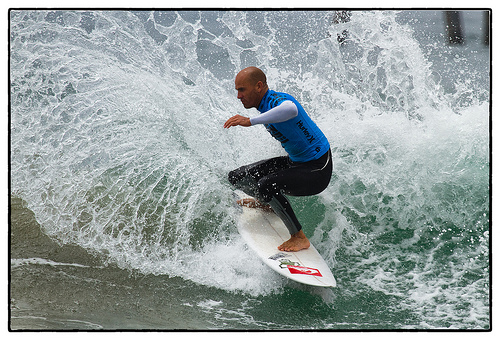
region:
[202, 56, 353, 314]
man surfing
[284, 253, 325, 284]
red logo on white board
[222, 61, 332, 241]
surfer in wet suit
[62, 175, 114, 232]
white and green ocean waves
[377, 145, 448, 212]
white and green ocean waves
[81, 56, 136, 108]
white and green ocean waves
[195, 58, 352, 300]
man riding on surf board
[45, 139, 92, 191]
white and green ocean waves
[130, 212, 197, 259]
white and green ocean waves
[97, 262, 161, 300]
white and green ocean waves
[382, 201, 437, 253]
white and green ocean waves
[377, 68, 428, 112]
white and green ocean waves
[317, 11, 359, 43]
white and green ocean waves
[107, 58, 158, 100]
white and green ocean waves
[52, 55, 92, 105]
white and green ocean waves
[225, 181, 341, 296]
white surfboard with red emblem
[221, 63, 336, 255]
man crouched on white surfboard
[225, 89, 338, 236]
blue white and black wetsuit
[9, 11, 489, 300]
large splash of crashing wave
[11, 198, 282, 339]
calm water preceding wave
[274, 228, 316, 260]
bare foot of man surfing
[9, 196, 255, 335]
dark brown ocean water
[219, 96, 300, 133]
curved hand at end of arm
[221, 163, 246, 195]
sharply bent knee of man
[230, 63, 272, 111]
head of surfer with balding hair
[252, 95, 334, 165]
a blue rash guard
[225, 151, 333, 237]
black pants of a wet suit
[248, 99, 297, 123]
a white wet suit sleeve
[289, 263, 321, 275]
a red logo on a surfboard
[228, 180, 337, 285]
a white surf board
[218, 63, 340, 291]
a man riding a wave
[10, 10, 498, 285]
a large spray of ocean water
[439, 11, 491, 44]
wooden pillars on a pier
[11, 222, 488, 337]
churning water ahead of a wave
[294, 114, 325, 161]
black design on the side of a shirt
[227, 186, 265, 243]
man surfing on a white surfboardman surfing on a white surfboardman surfing on a white surfboard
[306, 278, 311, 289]
man surfing on a white surfboardman surfing on a white surfboardman surfing on a white surfboard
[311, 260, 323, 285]
man surfing on a white surfboardman surfing on a white surfboardman surfing on a white surfboard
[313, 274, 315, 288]
man surfing on a white surfboardman surfing on a white surfboardman surfing on a white surfboard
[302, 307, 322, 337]
man surfing on a white surfboardman surfing on a white surfboardman surfing on a white surfboard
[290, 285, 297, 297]
man surfing on a white surfboardman surfing on a white surfboardman surfing on a white surfboard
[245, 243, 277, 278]
man surfing on a white surfboardman surfing on a white surfboardman surfing on a white surfboard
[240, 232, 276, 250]
man surfing on a white surfboardman surfing on a white surfboardman surfing on a white surfboard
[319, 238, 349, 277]
man surfing on a white surfboardman surfing on a white surfboardman surfing on a white surfboard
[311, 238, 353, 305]
man surfing on a white surfboardman surfing on a white surfboardman surfing on a white surfboard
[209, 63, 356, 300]
adult male surfer on board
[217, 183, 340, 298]
white surfboard in water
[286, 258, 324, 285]
red logo on white surfboard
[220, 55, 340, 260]
surfer squatted on board